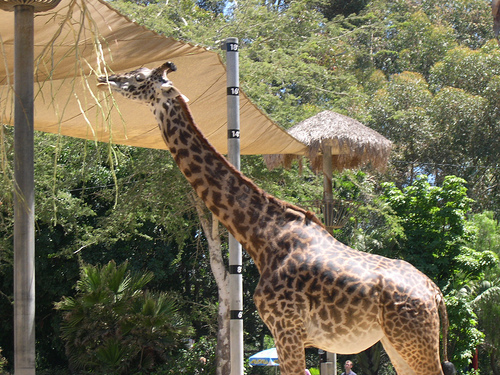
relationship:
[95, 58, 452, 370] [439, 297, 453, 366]
giraffe has tail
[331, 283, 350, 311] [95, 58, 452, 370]
spot on giraffe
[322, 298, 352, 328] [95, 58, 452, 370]
spot on giraffe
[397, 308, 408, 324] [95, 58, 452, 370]
spot on giraffe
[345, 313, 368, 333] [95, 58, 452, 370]
spot on giraffe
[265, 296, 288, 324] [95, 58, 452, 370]
spot on giraffe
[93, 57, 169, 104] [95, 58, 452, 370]
head of giraffe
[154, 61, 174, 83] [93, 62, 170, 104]
horns on h head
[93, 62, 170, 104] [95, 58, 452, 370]
head of giraffe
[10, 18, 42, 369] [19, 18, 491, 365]
pole in enclosure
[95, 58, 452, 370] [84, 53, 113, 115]
giraffe eating leaves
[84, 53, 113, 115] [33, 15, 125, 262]
leaves from a tree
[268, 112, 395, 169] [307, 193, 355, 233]
straw umbrella over food basket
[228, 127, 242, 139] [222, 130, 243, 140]
number on a strip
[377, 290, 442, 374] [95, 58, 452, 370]
legs of giraffe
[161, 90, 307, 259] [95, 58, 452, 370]
neck of giraffe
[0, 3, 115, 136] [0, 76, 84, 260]
giraffe feeder on pole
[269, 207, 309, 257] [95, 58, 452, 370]
brown spot on giraffe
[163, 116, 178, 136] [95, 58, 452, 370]
spot on giraffe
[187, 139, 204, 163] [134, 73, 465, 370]
brown spot on giraffe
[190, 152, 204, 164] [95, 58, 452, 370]
spot on giraffe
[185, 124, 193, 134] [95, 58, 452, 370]
spot on giraffe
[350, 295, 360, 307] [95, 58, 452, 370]
spot on giraffe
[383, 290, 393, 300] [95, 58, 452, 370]
spot on giraffe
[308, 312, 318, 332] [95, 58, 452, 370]
spot on giraffe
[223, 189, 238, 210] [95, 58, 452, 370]
spot on giraffe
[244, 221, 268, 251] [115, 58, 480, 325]
spot on giraffe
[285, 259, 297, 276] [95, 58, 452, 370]
spot on giraffe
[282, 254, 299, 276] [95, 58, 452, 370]
spot on giraffe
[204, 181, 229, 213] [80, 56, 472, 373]
spot on giraffe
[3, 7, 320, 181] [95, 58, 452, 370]
canopy over giraffe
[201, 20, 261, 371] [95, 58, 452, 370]
pole behind giraffe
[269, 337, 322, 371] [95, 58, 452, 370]
leg of giraffe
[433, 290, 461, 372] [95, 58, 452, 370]
tail of giraffe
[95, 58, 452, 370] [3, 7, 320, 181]
giraffe near canopy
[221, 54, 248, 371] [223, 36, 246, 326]
pole with numbers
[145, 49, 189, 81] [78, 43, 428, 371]
ear of giraffe